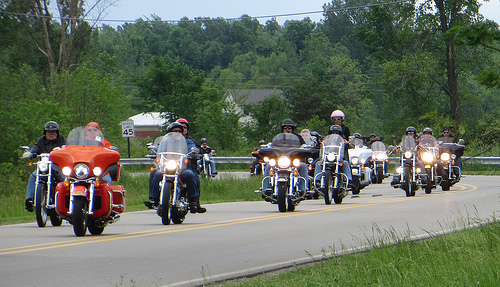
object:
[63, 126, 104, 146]
windshield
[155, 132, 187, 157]
windshield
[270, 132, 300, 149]
windshield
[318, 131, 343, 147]
windshield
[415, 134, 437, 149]
windshield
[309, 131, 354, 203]
motorcycle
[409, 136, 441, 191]
motorcycle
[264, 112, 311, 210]
motorcyclist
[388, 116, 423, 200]
motorcyclist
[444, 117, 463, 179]
motorcyclist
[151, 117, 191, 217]
motorcyclist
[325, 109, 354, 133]
people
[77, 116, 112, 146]
people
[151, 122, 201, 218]
people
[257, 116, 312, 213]
people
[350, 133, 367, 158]
people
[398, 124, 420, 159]
people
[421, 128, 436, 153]
people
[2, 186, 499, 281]
street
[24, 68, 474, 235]
motorcyclist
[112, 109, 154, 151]
sign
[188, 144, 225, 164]
mirror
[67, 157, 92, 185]
headlight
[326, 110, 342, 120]
helmet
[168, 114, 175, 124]
helmet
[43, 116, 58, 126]
helmet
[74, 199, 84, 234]
wheel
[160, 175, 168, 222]
wheel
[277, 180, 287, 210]
wheel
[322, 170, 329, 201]
wheel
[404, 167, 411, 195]
wheel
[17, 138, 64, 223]
motorcycle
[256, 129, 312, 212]
motorcycle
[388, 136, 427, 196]
motorcycle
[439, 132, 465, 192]
motorcycle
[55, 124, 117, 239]
motorcycle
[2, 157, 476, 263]
lines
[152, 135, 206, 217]
motorcycle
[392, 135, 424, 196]
motorcycle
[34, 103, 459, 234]
motorcycles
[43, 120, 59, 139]
head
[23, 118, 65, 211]
man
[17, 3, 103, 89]
tree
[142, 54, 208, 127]
tree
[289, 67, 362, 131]
tree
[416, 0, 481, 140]
tree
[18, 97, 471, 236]
people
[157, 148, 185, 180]
headlights